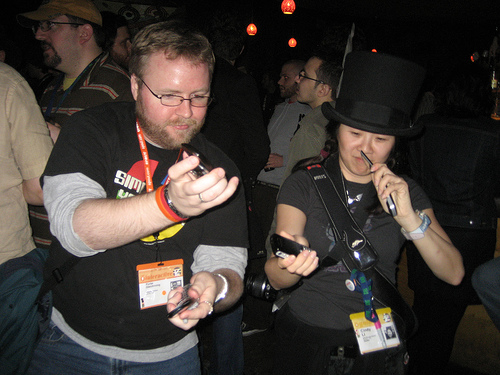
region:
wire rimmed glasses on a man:
[136, 66, 212, 111]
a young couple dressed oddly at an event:
[22, 25, 456, 342]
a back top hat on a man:
[326, 41, 413, 140]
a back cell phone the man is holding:
[266, 223, 322, 279]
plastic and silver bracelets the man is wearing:
[148, 182, 189, 231]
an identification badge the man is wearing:
[344, 301, 406, 355]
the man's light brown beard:
[139, 106, 206, 147]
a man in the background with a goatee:
[14, 7, 112, 108]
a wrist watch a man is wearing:
[401, 211, 438, 244]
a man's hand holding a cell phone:
[168, 147, 253, 209]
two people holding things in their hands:
[62, 43, 472, 346]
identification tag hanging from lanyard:
[125, 112, 187, 317]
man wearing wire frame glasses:
[120, 25, 240, 150]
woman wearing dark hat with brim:
[300, 35, 445, 180]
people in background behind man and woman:
[27, 6, 377, 196]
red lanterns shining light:
[225, 0, 340, 50]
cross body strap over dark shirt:
[255, 145, 421, 330]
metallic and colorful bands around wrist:
[145, 171, 190, 231]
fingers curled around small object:
[155, 142, 245, 222]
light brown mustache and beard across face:
[115, 98, 227, 151]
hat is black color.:
[330, 48, 440, 158]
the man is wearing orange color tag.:
[117, 100, 214, 315]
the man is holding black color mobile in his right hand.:
[156, 140, 249, 232]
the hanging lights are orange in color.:
[241, 0, 332, 88]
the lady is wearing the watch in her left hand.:
[400, 215, 450, 275]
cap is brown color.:
[21, 6, 101, 28]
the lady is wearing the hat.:
[323, 83, 430, 188]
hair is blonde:
[146, 28, 223, 75]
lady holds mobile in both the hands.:
[266, 172, 411, 268]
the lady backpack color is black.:
[302, 156, 344, 219]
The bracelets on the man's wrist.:
[156, 186, 184, 228]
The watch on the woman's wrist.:
[406, 199, 435, 248]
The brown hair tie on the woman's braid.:
[316, 146, 330, 161]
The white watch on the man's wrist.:
[212, 271, 229, 313]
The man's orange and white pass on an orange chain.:
[137, 261, 187, 315]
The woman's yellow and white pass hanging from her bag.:
[351, 307, 405, 355]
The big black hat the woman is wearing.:
[320, 46, 430, 139]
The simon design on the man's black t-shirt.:
[123, 147, 198, 249]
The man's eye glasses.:
[156, 86, 216, 112]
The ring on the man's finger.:
[198, 191, 205, 201]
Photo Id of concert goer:
[345, 282, 407, 357]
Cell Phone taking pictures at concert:
[350, 140, 406, 241]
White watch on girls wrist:
[400, 198, 447, 270]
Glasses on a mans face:
[132, 58, 224, 114]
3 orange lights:
[235, 1, 345, 60]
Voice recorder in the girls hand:
[262, 216, 324, 295]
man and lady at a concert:
[57, 10, 474, 316]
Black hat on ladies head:
[311, 59, 432, 151]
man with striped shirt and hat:
[29, 2, 137, 139]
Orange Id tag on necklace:
[130, 112, 200, 331]